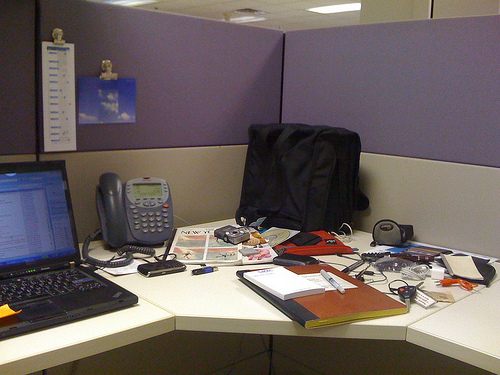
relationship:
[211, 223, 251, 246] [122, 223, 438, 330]
camera on desk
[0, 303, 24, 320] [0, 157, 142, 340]
orange sticker on laptop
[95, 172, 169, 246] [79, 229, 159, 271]
telephone has cord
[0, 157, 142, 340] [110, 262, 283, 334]
laptop on desk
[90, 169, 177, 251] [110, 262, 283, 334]
phone on desk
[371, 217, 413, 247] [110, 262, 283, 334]
item on desk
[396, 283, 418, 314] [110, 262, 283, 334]
keys on desk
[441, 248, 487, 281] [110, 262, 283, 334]
item on desk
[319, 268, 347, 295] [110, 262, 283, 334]
pen on desk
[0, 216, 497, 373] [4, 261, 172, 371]
desk has side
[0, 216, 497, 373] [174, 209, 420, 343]
desk has side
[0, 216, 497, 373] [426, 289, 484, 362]
desk has side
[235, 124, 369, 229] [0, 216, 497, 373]
black bag on desk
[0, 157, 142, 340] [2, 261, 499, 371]
laptop on desk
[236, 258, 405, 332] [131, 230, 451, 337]
book on desk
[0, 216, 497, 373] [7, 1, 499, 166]
desk has wall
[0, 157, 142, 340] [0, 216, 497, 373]
laptop on desk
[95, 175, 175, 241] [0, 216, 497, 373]
phone on desk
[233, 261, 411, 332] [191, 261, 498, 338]
book on top of desk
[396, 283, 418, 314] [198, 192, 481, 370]
keys on desk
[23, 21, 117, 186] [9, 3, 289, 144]
paper on wall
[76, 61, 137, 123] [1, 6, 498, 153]
paper on wall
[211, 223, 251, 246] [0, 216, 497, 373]
camera on top of desk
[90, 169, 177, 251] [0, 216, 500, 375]
phone on desk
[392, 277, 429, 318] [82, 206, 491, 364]
keys on table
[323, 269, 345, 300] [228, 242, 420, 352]
pen on notebook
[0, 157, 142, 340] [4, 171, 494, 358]
laptop on table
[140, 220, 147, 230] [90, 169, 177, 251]
key on phone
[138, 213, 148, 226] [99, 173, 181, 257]
key on phone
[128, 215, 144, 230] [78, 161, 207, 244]
key on phone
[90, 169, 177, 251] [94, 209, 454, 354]
phone on desk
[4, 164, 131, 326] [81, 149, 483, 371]
laptop on desk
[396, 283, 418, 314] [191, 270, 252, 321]
keys on top of desk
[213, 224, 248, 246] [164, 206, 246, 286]
camera on magazine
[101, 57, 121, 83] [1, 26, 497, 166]
clip on wall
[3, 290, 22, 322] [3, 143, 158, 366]
orange sticker on laptop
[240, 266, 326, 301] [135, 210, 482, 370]
notepad on desk